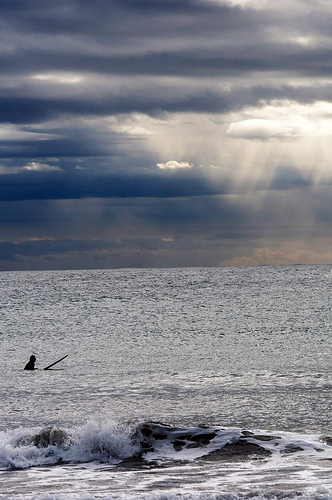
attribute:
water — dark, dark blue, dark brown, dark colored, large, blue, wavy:
[0, 265, 331, 499]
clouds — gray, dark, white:
[0, 1, 330, 272]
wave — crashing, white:
[1, 417, 331, 474]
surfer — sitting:
[23, 355, 37, 371]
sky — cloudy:
[1, 1, 331, 271]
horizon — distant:
[0, 246, 331, 289]